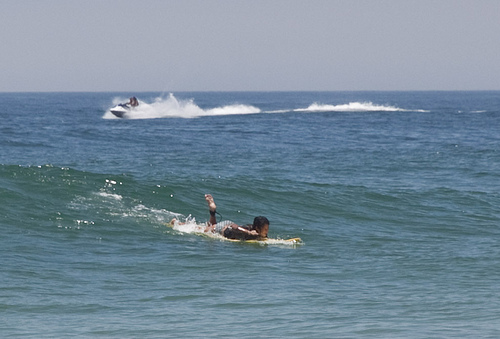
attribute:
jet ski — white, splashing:
[109, 102, 132, 118]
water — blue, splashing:
[1, 90, 498, 338]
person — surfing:
[170, 193, 305, 243]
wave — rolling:
[1, 163, 207, 216]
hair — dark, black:
[251, 215, 270, 230]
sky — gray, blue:
[1, 1, 499, 93]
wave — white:
[291, 101, 430, 113]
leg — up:
[207, 205, 216, 224]